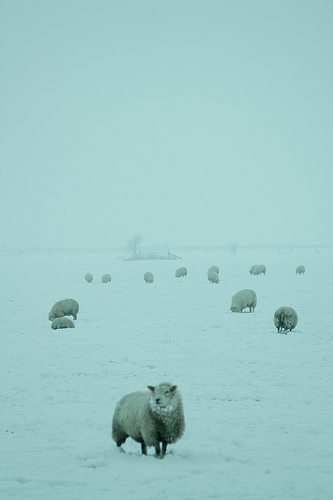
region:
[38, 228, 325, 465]
several sheet in the snow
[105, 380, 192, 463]
a sheep with a heavy coat of wool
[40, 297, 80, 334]
two sheep with thick wool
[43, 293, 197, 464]
three sheep with thick wool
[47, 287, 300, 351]
four sheep with thick wool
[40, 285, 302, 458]
five sheep with thick wool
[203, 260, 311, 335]
seven sheep with thick wool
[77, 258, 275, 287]
eight sheep with thick wool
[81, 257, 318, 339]
eleven sheep with thick wool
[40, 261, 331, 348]
thirteen sheep with thick wool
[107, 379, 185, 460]
Sheep on the snow.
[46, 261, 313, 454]
Herd of sheep.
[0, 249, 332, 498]
Snow covering the ground.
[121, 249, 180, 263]
Fence in the background.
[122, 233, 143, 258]
Tree in the background.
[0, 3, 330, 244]
Gray sky in the background.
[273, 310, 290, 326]
Back on the head of the sheep.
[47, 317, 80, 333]
Sheep laying down on the ground.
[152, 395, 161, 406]
Black nose on the sheep.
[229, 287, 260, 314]
Gray wool on the sheep.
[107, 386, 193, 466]
a sheep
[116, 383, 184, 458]
a sheep standing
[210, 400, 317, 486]
the snow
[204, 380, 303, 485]
the snow is white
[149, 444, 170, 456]
the sheeps legs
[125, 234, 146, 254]
tree branches on the tree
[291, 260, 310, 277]
sheep in the snow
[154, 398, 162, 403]
the sheep has a black nose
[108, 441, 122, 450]
the sheeps leg is in snow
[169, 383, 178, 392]
the ear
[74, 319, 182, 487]
These are sheep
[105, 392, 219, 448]
The sheep has wool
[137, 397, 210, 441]
The sheep is covered in snow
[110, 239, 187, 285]
This is a bridge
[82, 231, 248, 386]
The picture is white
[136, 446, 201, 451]
These are legs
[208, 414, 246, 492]
This is a footprint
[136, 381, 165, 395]
This is an ear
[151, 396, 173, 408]
This is a nose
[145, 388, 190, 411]
This is an eye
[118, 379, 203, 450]
A brown wool sheep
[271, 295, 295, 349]
A brown wool sheep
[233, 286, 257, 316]
A brown wool sheep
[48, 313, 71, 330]
A brown wool sheep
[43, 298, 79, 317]
A brown wool sheep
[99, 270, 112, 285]
A brown wool sheep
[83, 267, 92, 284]
A brown wool sheep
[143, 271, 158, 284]
A brown wool sheep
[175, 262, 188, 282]
A brown wool sheep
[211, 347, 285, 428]
A snow filled field